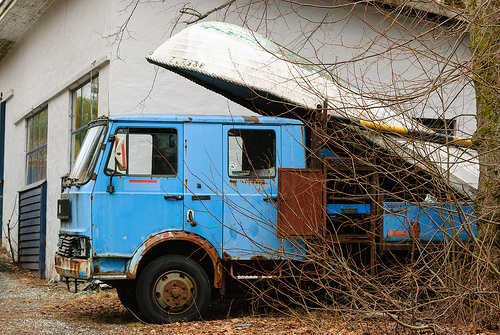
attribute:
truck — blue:
[16, 85, 421, 289]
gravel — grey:
[5, 280, 60, 333]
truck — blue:
[53, 112, 478, 323]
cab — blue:
[53, 115, 313, 322]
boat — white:
[151, 24, 496, 197]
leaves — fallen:
[48, 284, 453, 333]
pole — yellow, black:
[314, 105, 483, 153]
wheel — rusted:
[128, 247, 218, 328]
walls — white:
[51, 0, 105, 54]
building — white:
[0, 2, 482, 292]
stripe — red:
[127, 174, 159, 186]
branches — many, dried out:
[185, 2, 499, 333]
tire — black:
[100, 208, 240, 330]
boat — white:
[145, 19, 475, 196]